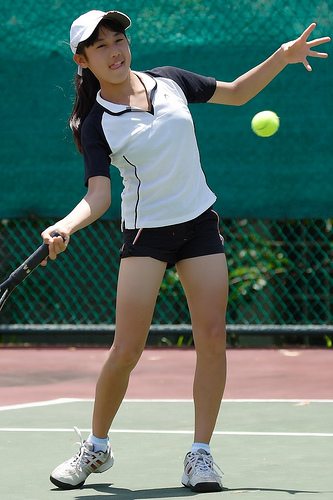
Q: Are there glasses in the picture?
A: No, there are no glasses.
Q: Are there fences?
A: Yes, there is a fence.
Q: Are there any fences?
A: Yes, there is a fence.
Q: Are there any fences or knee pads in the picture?
A: Yes, there is a fence.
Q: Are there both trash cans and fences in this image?
A: No, there is a fence but no trash cans.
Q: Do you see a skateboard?
A: No, there are no skateboards.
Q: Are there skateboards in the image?
A: No, there are no skateboards.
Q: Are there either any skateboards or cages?
A: No, there are no skateboards or cages.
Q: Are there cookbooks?
A: No, there are no cookbooks.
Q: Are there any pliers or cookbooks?
A: No, there are no cookbooks or pliers.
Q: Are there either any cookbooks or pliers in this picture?
A: No, there are no cookbooks or pliers.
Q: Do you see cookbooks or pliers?
A: No, there are no cookbooks or pliers.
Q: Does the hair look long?
A: Yes, the hair is long.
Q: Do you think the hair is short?
A: No, the hair is long.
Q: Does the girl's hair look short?
A: No, the hair is long.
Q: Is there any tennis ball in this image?
A: Yes, there is a tennis ball.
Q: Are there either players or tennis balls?
A: Yes, there is a tennis ball.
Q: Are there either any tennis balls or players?
A: Yes, there is a tennis ball.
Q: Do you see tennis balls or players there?
A: Yes, there is a tennis ball.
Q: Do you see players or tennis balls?
A: Yes, there is a tennis ball.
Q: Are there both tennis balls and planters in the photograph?
A: No, there is a tennis ball but no planters.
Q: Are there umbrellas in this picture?
A: No, there are no umbrellas.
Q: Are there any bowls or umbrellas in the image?
A: No, there are no umbrellas or bowls.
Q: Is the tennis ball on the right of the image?
A: Yes, the tennis ball is on the right of the image.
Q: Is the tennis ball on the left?
A: No, the tennis ball is on the right of the image.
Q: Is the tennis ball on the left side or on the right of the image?
A: The tennis ball is on the right of the image.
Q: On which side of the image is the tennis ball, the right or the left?
A: The tennis ball is on the right of the image.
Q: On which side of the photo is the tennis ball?
A: The tennis ball is on the right of the image.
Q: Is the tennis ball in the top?
A: Yes, the tennis ball is in the top of the image.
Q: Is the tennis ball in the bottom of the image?
A: No, the tennis ball is in the top of the image.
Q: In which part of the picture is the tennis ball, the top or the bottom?
A: The tennis ball is in the top of the image.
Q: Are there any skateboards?
A: No, there are no skateboards.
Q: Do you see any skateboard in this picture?
A: No, there are no skateboards.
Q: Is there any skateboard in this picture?
A: No, there are no skateboards.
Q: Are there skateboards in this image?
A: No, there are no skateboards.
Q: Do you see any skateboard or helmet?
A: No, there are no skateboards or helmets.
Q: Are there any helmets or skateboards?
A: No, there are no skateboards or helmets.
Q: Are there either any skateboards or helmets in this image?
A: No, there are no skateboards or helmets.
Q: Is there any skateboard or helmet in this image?
A: No, there are no skateboards or helmets.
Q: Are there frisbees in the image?
A: No, there are no frisbees.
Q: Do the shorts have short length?
A: Yes, the shorts are short.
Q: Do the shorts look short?
A: Yes, the shorts are short.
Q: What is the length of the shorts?
A: The shorts are short.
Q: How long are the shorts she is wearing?
A: The shorts are short.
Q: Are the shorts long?
A: No, the shorts are short.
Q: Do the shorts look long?
A: No, the shorts are short.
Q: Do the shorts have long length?
A: No, the shorts are short.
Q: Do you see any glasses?
A: No, there are no glasses.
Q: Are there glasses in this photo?
A: No, there are no glasses.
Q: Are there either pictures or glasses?
A: No, there are no glasses or pictures.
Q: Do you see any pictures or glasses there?
A: No, there are no glasses or pictures.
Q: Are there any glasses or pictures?
A: No, there are no glasses or pictures.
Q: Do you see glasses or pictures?
A: No, there are no glasses or pictures.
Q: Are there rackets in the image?
A: Yes, there is a racket.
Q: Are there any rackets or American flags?
A: Yes, there is a racket.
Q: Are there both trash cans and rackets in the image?
A: No, there is a racket but no trash cans.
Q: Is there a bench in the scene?
A: No, there are no benches.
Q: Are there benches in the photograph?
A: No, there are no benches.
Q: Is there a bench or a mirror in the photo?
A: No, there are no benches or mirrors.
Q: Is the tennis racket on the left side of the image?
A: Yes, the tennis racket is on the left of the image.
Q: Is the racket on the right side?
A: No, the racket is on the left of the image.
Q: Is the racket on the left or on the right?
A: The racket is on the left of the image.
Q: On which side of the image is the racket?
A: The racket is on the left of the image.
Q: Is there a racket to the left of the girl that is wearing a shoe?
A: Yes, there is a racket to the left of the girl.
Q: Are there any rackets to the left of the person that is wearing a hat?
A: Yes, there is a racket to the left of the girl.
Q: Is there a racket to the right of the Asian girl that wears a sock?
A: No, the racket is to the left of the girl.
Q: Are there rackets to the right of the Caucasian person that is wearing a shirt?
A: No, the racket is to the left of the girl.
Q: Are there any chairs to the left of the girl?
A: No, there is a racket to the left of the girl.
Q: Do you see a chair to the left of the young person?
A: No, there is a racket to the left of the girl.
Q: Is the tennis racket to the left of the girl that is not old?
A: Yes, the tennis racket is to the left of the girl.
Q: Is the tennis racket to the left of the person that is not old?
A: Yes, the tennis racket is to the left of the girl.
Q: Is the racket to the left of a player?
A: No, the racket is to the left of the girl.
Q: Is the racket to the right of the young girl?
A: No, the racket is to the left of the girl.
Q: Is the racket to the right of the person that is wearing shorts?
A: No, the racket is to the left of the girl.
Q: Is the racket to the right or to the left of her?
A: The racket is to the left of the girl.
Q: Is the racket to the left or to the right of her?
A: The racket is to the left of the girl.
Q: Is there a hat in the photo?
A: Yes, there is a hat.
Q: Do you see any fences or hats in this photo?
A: Yes, there is a hat.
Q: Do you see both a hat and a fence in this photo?
A: Yes, there are both a hat and a fence.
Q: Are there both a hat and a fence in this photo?
A: Yes, there are both a hat and a fence.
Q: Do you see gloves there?
A: No, there are no gloves.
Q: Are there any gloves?
A: No, there are no gloves.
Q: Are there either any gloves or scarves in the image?
A: No, there are no gloves or scarves.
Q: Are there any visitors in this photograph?
A: No, there are no visitors.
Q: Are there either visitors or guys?
A: No, there are no visitors or guys.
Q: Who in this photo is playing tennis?
A: The girl is playing tennis.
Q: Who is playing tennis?
A: The girl is playing tennis.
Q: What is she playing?
A: The girl is playing tennis.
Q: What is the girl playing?
A: The girl is playing tennis.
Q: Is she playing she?
A: Yes, the girl is playing tennis.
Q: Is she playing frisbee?
A: No, the girl is playing tennis.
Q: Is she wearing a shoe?
A: Yes, the girl is wearing a shoe.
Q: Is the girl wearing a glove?
A: No, the girl is wearing a shoe.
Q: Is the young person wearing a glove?
A: No, the girl is wearing a shoe.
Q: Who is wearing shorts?
A: The girl is wearing shorts.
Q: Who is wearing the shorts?
A: The girl is wearing shorts.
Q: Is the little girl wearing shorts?
A: Yes, the girl is wearing shorts.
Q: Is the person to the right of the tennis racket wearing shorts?
A: Yes, the girl is wearing shorts.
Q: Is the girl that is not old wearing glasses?
A: No, the girl is wearing shorts.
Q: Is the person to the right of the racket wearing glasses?
A: No, the girl is wearing shorts.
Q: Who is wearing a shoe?
A: The girl is wearing a shoe.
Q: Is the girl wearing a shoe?
A: Yes, the girl is wearing a shoe.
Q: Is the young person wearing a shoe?
A: Yes, the girl is wearing a shoe.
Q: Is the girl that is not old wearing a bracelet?
A: No, the girl is wearing a shoe.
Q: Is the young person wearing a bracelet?
A: No, the girl is wearing a shoe.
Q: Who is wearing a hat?
A: The girl is wearing a hat.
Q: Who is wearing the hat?
A: The girl is wearing a hat.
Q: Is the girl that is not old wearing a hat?
A: Yes, the girl is wearing a hat.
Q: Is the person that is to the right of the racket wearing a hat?
A: Yes, the girl is wearing a hat.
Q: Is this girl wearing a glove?
A: No, the girl is wearing a hat.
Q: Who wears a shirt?
A: The girl wears a shirt.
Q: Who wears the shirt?
A: The girl wears a shirt.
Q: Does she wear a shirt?
A: Yes, the girl wears a shirt.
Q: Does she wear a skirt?
A: No, the girl wears a shirt.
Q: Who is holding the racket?
A: The girl is holding the racket.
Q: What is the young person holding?
A: The girl is holding the tennis racket.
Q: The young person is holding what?
A: The girl is holding the tennis racket.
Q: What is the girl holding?
A: The girl is holding the tennis racket.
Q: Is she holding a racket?
A: Yes, the girl is holding a racket.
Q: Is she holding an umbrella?
A: No, the girl is holding a racket.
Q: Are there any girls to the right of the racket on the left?
A: Yes, there is a girl to the right of the racket.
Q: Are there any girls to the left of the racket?
A: No, the girl is to the right of the racket.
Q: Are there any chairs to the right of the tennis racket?
A: No, there is a girl to the right of the tennis racket.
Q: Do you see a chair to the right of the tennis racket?
A: No, there is a girl to the right of the tennis racket.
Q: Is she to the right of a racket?
A: Yes, the girl is to the right of a racket.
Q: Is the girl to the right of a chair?
A: No, the girl is to the right of a racket.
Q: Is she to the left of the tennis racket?
A: No, the girl is to the right of the tennis racket.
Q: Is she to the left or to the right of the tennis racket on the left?
A: The girl is to the right of the tennis racket.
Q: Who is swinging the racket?
A: The girl is swinging the racket.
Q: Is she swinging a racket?
A: Yes, the girl is swinging a racket.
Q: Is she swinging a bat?
A: No, the girl is swinging a racket.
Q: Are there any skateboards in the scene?
A: No, there are no skateboards.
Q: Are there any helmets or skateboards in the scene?
A: No, there are no skateboards or helmets.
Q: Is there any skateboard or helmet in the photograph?
A: No, there are no skateboards or helmets.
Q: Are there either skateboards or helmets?
A: No, there are no skateboards or helmets.